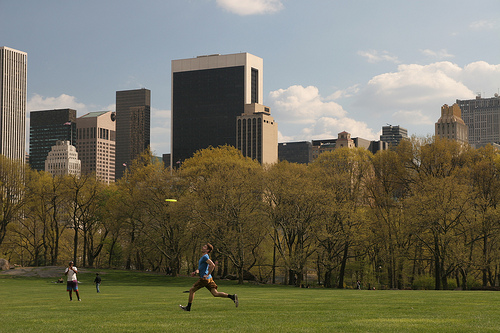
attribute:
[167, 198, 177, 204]
frisbee — yellow, small, flying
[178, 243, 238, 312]
man — running, young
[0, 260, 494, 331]
park — large, green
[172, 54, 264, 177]
building — tall, black, white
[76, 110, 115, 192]
building — gray, pointy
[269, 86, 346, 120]
cloud — fluffy, white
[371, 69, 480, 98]
cloud — fluffy, white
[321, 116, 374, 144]
cloud — fluffy, white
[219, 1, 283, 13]
cloud — fluffy, white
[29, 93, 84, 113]
cloud — fluffy, white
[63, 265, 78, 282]
shirt — white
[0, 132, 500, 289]
trees — row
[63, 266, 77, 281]
t-shirt — white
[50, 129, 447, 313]
park — city park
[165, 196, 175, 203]
disc — yellow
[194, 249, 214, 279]
shirt — blue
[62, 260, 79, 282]
shirt — white, short sleeve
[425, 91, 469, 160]
building — brown, small, Pointy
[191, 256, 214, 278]
tee shirt — blue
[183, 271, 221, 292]
shorts — tan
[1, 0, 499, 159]
sky — blue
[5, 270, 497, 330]
grass — green, short, lush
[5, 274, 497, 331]
field — large, open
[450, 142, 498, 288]
tree — large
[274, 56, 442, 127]
clouds — white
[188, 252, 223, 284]
t-shirt — blue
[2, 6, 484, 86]
sky — blue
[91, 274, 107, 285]
jacket — dark colored